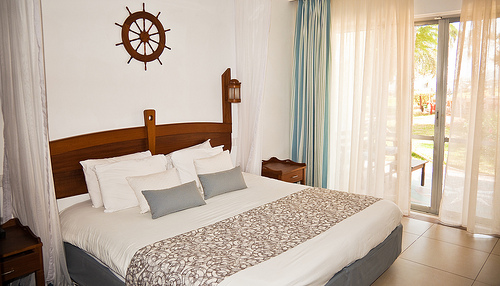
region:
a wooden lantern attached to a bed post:
[226, 78, 241, 103]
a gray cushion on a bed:
[143, 181, 208, 218]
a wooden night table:
[262, 156, 307, 183]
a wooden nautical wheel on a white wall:
[112, 4, 173, 69]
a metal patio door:
[404, 18, 462, 216]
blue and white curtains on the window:
[291, 0, 499, 235]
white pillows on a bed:
[81, 150, 179, 215]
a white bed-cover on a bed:
[60, 169, 402, 284]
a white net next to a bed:
[0, 1, 76, 284]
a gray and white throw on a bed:
[125, 183, 378, 284]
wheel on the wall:
[111, 3, 176, 70]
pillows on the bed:
[78, 134, 246, 216]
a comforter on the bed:
[61, 164, 400, 284]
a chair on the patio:
[391, 143, 426, 188]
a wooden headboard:
[50, 65, 242, 195]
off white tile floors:
[371, 210, 499, 282]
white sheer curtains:
[333, 5, 499, 235]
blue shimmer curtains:
[292, 0, 333, 185]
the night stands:
[1, 154, 310, 281]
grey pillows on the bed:
[143, 165, 246, 215]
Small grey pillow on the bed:
[143, 183, 201, 218]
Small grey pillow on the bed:
[203, 171, 243, 196]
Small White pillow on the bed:
[120, 173, 178, 215]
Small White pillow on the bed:
[189, 155, 239, 184]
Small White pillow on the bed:
[88, 162, 167, 212]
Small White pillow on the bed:
[174, 150, 229, 198]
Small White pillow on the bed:
[153, 134, 240, 196]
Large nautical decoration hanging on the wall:
[100, 2, 179, 68]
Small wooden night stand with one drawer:
[258, 134, 310, 192]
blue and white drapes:
[291, 40, 340, 107]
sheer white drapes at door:
[342, 33, 403, 118]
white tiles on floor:
[418, 229, 473, 279]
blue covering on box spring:
[373, 238, 407, 278]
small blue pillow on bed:
[140, 183, 216, 218]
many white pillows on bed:
[77, 151, 187, 191]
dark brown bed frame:
[48, 116, 238, 181]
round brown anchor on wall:
[102, 6, 174, 68]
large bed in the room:
[19, 111, 421, 283]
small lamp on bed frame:
[221, 66, 246, 103]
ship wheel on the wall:
[109, 1, 182, 74]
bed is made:
[43, 68, 425, 283]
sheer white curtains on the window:
[327, 0, 499, 234]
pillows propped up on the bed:
[74, 135, 254, 221]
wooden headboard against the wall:
[29, 54, 251, 205]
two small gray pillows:
[140, 160, 253, 224]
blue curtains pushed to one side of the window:
[294, 0, 335, 200]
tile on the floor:
[370, 198, 497, 285]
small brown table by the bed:
[0, 213, 54, 284]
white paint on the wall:
[36, 2, 236, 145]